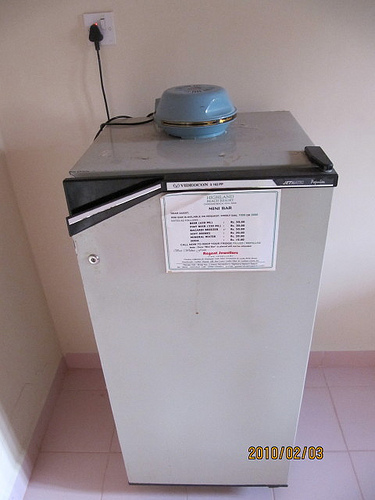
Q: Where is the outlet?
A: On the wall.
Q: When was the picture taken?
A: 2/3/2010.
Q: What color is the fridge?
A: Black and white.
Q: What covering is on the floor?
A: Tiles.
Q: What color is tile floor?
A: White.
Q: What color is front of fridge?
A: Grey and black.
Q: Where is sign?
A: On fridge door.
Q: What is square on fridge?
A: White logo.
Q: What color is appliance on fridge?
A: Blue.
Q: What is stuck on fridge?
A: Paper.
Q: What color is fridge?
A: Black and white.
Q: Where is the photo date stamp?
A: The bottom right.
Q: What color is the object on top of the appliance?
A: Blue.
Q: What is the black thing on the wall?
A: A plug and cord.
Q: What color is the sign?
A: White.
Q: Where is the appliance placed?
A: In a corner.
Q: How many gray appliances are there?
A: 1.